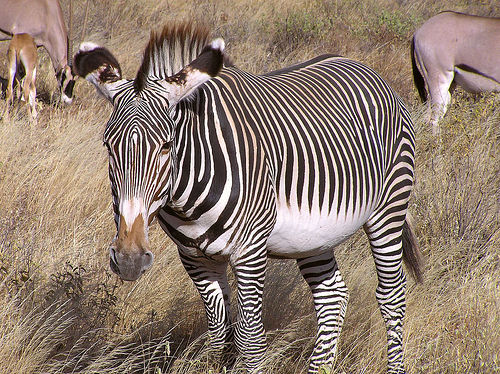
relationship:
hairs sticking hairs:
[141, 40, 174, 64] [130, 17, 244, 84]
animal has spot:
[63, 21, 426, 365] [116, 207, 146, 249]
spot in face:
[116, 207, 146, 249] [99, 91, 180, 282]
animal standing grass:
[63, 21, 426, 365] [8, 146, 67, 328]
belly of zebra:
[254, 193, 368, 263] [64, 10, 444, 370]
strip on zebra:
[368, 226, 409, 243] [64, 10, 444, 370]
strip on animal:
[373, 254, 405, 269] [63, 21, 426, 365]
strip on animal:
[371, 221, 404, 240] [63, 21, 426, 365]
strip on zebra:
[369, 210, 409, 224] [64, 10, 444, 370]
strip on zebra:
[383, 180, 406, 204] [64, 10, 444, 370]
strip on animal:
[298, 256, 335, 270] [63, 21, 426, 365]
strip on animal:
[300, 265, 343, 284] [63, 21, 426, 365]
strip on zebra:
[317, 306, 343, 316] [64, 10, 444, 370]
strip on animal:
[188, 270, 218, 282] [63, 21, 426, 365]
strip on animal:
[233, 261, 267, 281] [63, 21, 426, 365]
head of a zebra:
[58, 35, 229, 275] [64, 10, 444, 370]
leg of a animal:
[179, 252, 229, 368] [63, 21, 426, 365]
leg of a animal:
[230, 253, 270, 364] [63, 21, 426, 365]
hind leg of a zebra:
[296, 246, 349, 374] [64, 10, 444, 370]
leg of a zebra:
[376, 213, 406, 367] [72, 19, 417, 369]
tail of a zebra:
[393, 205, 427, 294] [88, 27, 437, 360]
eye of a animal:
[101, 140, 115, 156] [63, 21, 426, 365]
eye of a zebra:
[156, 137, 173, 157] [88, 27, 437, 360]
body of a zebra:
[194, 52, 395, 258] [64, 10, 444, 370]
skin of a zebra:
[265, 71, 400, 171] [64, 10, 444, 370]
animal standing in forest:
[7, 30, 47, 130] [0, 5, 495, 368]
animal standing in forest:
[409, 6, 497, 127] [0, 5, 495, 368]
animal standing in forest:
[83, 30, 428, 363] [0, 5, 495, 368]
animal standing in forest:
[6, 6, 76, 100] [0, 5, 495, 368]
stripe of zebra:
[319, 76, 365, 144] [88, 27, 437, 360]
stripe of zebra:
[305, 95, 337, 142] [88, 27, 437, 360]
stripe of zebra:
[295, 109, 325, 163] [88, 27, 437, 360]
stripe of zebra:
[284, 110, 322, 186] [88, 27, 437, 360]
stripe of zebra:
[294, 101, 335, 176] [88, 27, 437, 360]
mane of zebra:
[133, 24, 221, 81] [64, 10, 444, 370]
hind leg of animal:
[296, 246, 349, 374] [63, 21, 426, 365]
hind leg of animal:
[364, 197, 411, 374] [63, 21, 426, 365]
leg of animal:
[230, 245, 268, 360] [63, 21, 426, 365]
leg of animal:
[179, 252, 229, 368] [63, 21, 426, 365]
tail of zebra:
[399, 213, 426, 282] [64, 10, 444, 370]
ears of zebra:
[74, 34, 228, 95] [64, 10, 444, 370]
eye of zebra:
[156, 137, 173, 157] [64, 10, 444, 370]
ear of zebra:
[156, 34, 228, 94] [64, 10, 444, 370]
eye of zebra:
[159, 142, 175, 154] [64, 10, 444, 370]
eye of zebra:
[101, 140, 115, 156] [64, 10, 444, 370]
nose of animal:
[110, 247, 150, 279] [63, 21, 426, 365]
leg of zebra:
[230, 253, 270, 364] [64, 10, 444, 370]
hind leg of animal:
[369, 197, 405, 371] [63, 21, 426, 365]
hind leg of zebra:
[296, 246, 348, 371] [72, 19, 417, 369]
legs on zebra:
[183, 220, 413, 367] [64, 10, 444, 370]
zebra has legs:
[64, 10, 444, 370] [183, 220, 413, 367]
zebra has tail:
[64, 10, 444, 370] [390, 197, 435, 289]